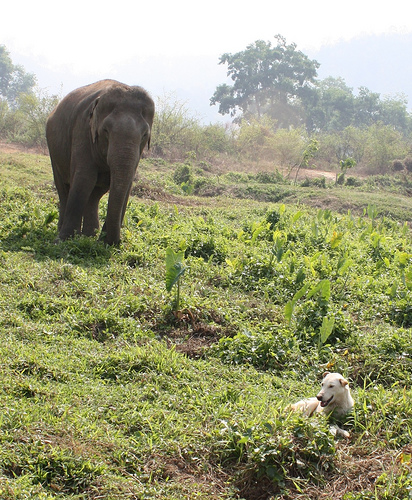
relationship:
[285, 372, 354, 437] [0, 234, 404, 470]
dog laying in grass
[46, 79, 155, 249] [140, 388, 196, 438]
elephant walking on grass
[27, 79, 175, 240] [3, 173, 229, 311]
elephant on weeds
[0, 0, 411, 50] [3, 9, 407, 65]
cloud on sky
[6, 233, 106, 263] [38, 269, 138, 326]
shadow on ground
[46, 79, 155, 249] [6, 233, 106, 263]
elephant has shadow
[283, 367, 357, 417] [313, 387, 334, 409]
dog has mouth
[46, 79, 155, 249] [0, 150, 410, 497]
elephant on grass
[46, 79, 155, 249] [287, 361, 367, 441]
elephant behind dog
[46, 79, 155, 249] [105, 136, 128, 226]
elephant has trunk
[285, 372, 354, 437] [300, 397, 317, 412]
dog has fur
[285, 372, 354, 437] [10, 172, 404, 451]
dog on grass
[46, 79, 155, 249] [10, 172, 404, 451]
elephant on grass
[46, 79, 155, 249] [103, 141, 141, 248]
elephant has trunk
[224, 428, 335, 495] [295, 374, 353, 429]
grass front dog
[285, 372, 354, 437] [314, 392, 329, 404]
dog has nose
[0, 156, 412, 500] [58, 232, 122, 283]
grass on ground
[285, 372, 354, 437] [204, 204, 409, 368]
dog reclined in vegetation